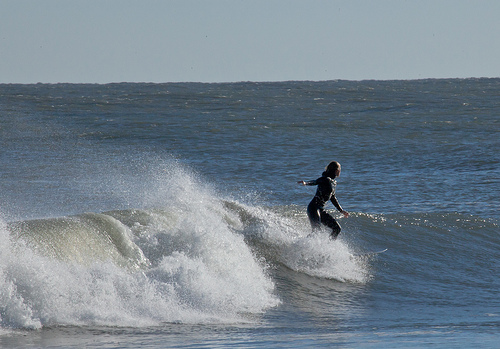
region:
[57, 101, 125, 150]
ripples in ocean water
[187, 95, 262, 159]
ripples in ocean water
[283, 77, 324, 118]
ripples in ocean water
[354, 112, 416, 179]
ripples in ocean water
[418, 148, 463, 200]
ripples in ocean water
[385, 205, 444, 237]
ripples in ocean water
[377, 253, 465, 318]
ripples in ocean water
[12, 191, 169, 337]
waves crashing in water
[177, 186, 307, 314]
waves crashing in water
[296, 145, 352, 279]
woman riding a surfboard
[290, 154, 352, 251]
a woman surfing on the water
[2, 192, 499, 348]
a woman surfing on a large wave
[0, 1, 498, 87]
a clear sky in the picture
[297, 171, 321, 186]
the arm of a woman surfing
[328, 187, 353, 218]
the arm of a woman surfing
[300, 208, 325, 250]
the leg of a woman surfing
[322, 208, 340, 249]
the leg of a woman surfing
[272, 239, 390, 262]
a surf board on the water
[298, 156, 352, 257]
a woman in a dark swim suit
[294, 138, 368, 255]
woman on a surfboard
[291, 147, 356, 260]
woman on a surfboard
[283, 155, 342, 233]
woman on a surfboard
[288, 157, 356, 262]
woman on a surfboard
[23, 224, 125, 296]
waves crashing into the ocean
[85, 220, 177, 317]
waves crashing into the ocean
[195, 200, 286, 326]
waves crashing into the ocean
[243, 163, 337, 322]
waves crashing into the ocean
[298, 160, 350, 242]
a female surfer on a wave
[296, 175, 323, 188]
the surfers extended arm for balance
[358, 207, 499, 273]
the wave in front of the surfer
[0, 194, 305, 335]
the wave crest crashing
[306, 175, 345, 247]
the surfer is wearing a full wetsuit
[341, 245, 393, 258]
a white surfboard cutting through the wave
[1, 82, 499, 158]
the rough water in the ocean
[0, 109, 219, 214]
spray from the wave crashing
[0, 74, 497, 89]
rough water in the horizon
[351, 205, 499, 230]
the sun reflecting on the water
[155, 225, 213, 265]
Churning white ocean water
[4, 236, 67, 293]
Churning white ocean surf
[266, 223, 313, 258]
Churning white ocean surf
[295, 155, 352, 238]
Athletic surfer on ocean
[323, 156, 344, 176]
Head of athletic surfer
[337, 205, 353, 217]
Hand of athletic surfer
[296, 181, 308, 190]
Hand of athletic surfer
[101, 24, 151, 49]
Hazy blue sky above beach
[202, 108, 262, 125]
Ocean water in distance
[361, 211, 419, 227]
crest of small wave near surfer